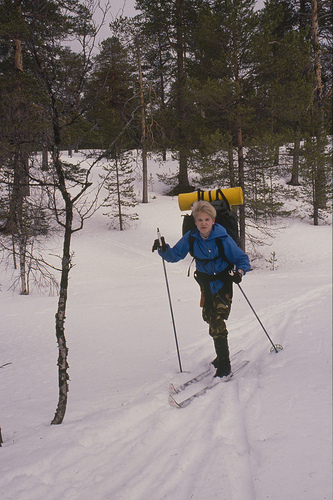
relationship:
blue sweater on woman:
[158, 222, 251, 301] [147, 200, 252, 380]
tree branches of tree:
[251, 176, 297, 218] [128, 39, 152, 208]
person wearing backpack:
[150, 199, 249, 378] [180, 191, 242, 239]